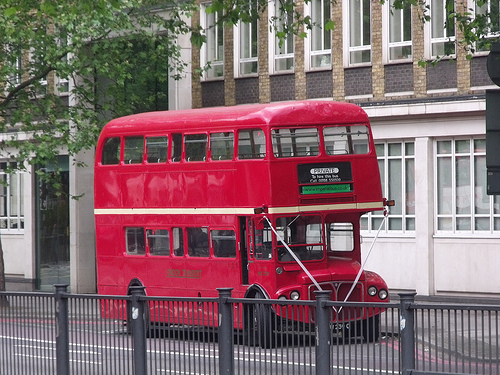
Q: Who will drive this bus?
A: The bus driver.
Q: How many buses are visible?
A: One.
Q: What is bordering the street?
A: A fence.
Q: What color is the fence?
A: Grey.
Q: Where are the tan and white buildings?
A: On the far side of the road.